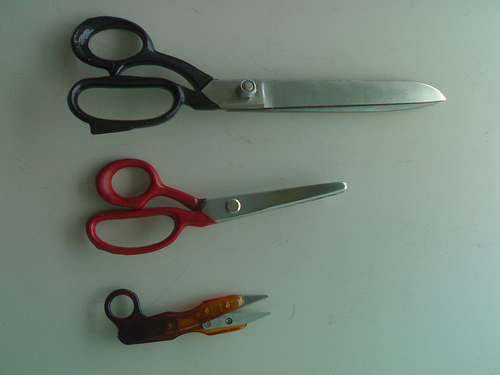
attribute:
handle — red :
[89, 152, 218, 263]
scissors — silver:
[32, 10, 453, 142]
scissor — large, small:
[65, 14, 447, 134]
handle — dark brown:
[91, 271, 178, 367]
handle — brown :
[102, 285, 184, 349]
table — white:
[3, 5, 498, 373]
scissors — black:
[66, 15, 448, 135]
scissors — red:
[83, 156, 350, 256]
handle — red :
[85, 157, 216, 254]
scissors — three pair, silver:
[25, 27, 423, 372]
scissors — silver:
[161, 67, 446, 130]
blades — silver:
[227, 52, 441, 98]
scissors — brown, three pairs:
[63, 18, 462, 351]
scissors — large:
[54, 10, 457, 117]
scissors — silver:
[72, 133, 383, 266]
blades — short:
[186, 286, 274, 340]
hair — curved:
[212, 336, 273, 375]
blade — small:
[184, 282, 273, 359]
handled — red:
[63, 148, 206, 263]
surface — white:
[41, 51, 460, 297]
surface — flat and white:
[43, 126, 440, 369]